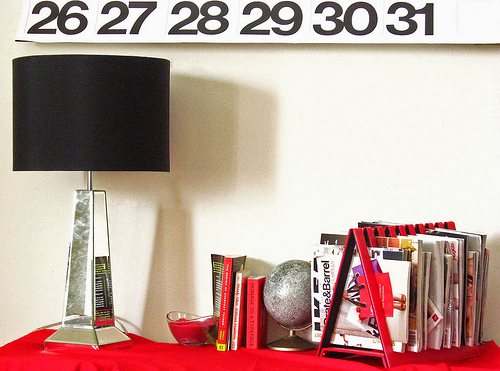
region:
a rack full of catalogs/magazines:
[306, 212, 499, 364]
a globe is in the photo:
[252, 250, 352, 363]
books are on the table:
[200, 238, 287, 353]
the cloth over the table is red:
[8, 297, 288, 367]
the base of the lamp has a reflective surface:
[0, 44, 229, 356]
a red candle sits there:
[158, 303, 233, 350]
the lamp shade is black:
[8, 41, 210, 189]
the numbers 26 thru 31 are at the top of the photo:
[23, 2, 454, 49]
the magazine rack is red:
[331, 193, 486, 351]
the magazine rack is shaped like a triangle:
[301, 215, 498, 367]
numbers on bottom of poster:
[28, 0, 441, 45]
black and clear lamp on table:
[9, 52, 172, 356]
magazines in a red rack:
[311, 212, 490, 366]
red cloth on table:
[0, 327, 498, 369]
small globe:
[263, 256, 313, 350]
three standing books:
[208, 250, 267, 352]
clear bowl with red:
[160, 307, 218, 345]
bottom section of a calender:
[12, 0, 499, 45]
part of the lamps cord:
[33, 321, 65, 330]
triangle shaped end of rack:
[316, 227, 401, 367]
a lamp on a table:
[0, 19, 445, 370]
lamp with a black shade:
[10, 5, 293, 360]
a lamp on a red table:
[11, 25, 203, 365]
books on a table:
[147, 197, 473, 362]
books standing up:
[169, 207, 327, 349]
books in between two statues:
[145, 185, 332, 367]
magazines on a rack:
[311, 199, 498, 368]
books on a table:
[15, 33, 406, 369]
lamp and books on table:
[11, 4, 493, 363]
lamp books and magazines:
[15, 24, 496, 356]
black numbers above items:
[17, 0, 437, 37]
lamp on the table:
[10, 53, 167, 350]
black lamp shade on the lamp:
[12, 52, 170, 172]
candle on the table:
[165, 309, 217, 344]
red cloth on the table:
[0, 327, 497, 369]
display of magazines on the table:
[312, 220, 489, 367]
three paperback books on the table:
[207, 250, 264, 351]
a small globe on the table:
[264, 258, 314, 352]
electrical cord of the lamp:
[34, 315, 127, 335]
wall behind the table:
[0, 0, 497, 352]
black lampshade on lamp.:
[30, 71, 158, 126]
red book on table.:
[246, 271, 263, 350]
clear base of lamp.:
[71, 193, 101, 306]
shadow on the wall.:
[192, 90, 257, 192]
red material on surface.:
[150, 348, 198, 363]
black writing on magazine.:
[322, 260, 329, 286]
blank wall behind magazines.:
[354, 130, 435, 186]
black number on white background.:
[312, 5, 375, 38]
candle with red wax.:
[182, 315, 209, 336]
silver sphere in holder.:
[279, 264, 307, 314]